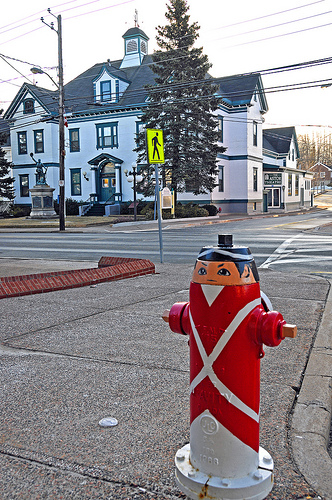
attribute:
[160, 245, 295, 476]
firehydrant — red, white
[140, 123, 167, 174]
sign — yellow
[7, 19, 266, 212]
house — green, white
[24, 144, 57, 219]
statue — stone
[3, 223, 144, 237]
sidewalk — cement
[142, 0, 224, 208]
tree — large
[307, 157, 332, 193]
house — brown, white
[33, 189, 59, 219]
base — metal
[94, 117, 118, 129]
trim — green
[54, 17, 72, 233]
telephone pole — wooden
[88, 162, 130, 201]
door — green